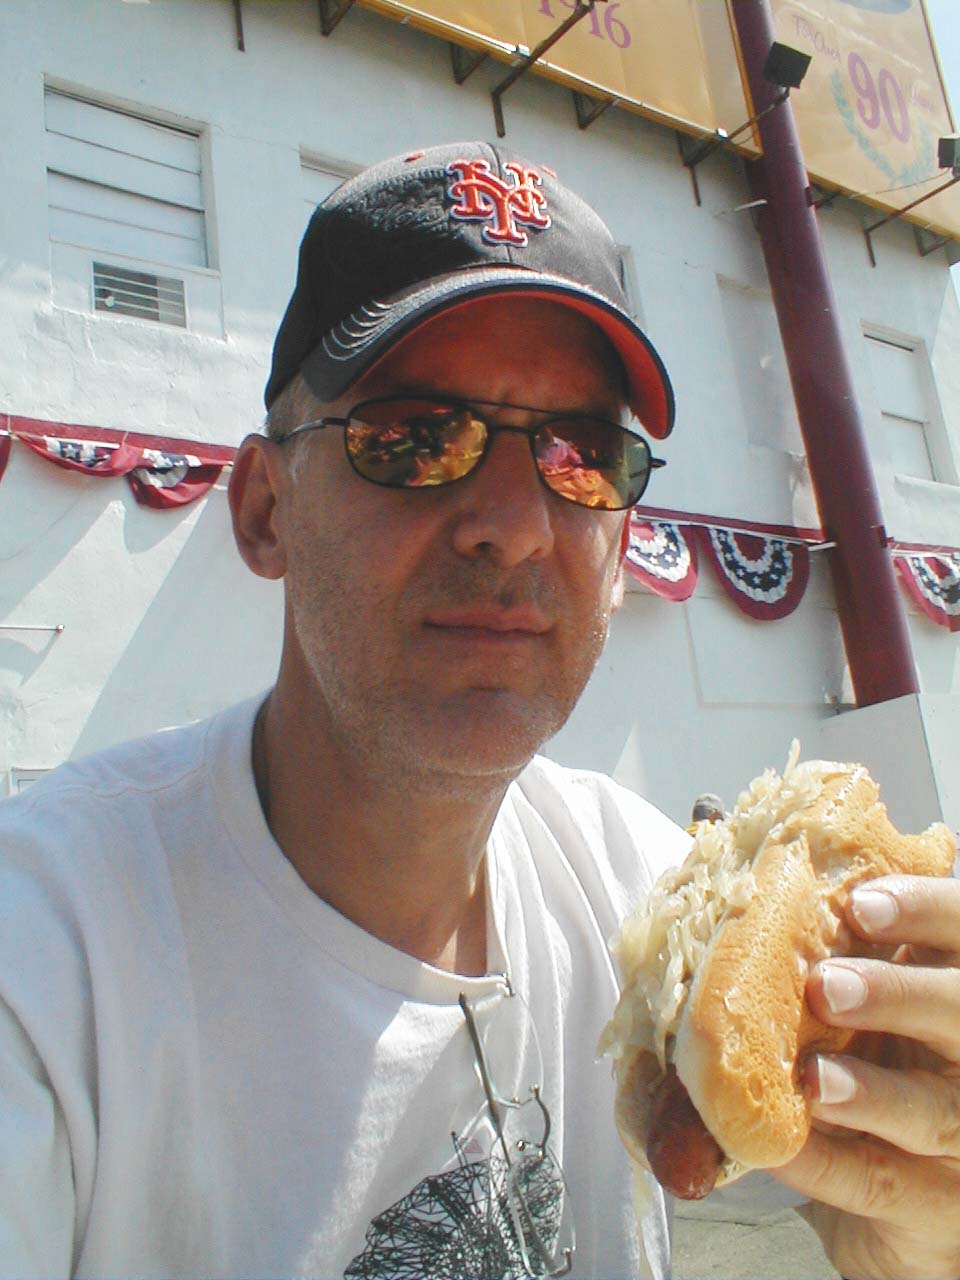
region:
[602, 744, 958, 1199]
a hot dog with wiener and sauerkraut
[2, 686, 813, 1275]
a white shirt with a black logo on it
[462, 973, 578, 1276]
a pair of glasses with silver frame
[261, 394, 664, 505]
sunglasses with black frame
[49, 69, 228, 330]
a white vent below a window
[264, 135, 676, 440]
a black cap with an orange logo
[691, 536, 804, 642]
flag on the building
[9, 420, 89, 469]
flag on the building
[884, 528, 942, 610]
flag on the building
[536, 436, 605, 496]
glasses on the man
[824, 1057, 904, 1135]
finger on the hand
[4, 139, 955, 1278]
a man wearing a baseball hat with the initials N and Y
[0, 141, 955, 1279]
man has a pair of glasses hanging from his shirt collar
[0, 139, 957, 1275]
man's sunglasses are reflective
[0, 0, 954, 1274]
tall white wall behind man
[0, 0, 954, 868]
wall has patriotic bunting on it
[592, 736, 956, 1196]
hotdog bun has a bite-sized piece missing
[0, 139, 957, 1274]
man's face is unshaven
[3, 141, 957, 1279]
man's white shirt has a black design on it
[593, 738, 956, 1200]
hot dog with saurkraut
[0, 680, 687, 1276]
white t-shirt with black design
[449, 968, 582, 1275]
dangling reading glasses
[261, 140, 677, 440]
New York ball cap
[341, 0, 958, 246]
large yellow billboard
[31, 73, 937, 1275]
man eating a hot dog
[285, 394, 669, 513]
reflective sunglasses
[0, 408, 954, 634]
red, white, and blue patriotic decorations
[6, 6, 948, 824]
building painted white and decorated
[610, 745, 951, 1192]
A partially eaten hot dog.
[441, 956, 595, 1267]
Eyeglasses hanging from neck of shirt.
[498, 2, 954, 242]
Large yellow and red sign.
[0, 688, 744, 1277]
A white tee shirt.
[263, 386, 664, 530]
Dark framed sunglasses.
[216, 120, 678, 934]
Man wearing black cap.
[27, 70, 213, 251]
A shuttered window.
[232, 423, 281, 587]
A person's right ear.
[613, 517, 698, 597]
red white and blue flag behind the man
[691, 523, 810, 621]
red white and blue flag behind the man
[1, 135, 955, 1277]
A man wearing a New York hat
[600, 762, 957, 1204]
A hot dog missing a bite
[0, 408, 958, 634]
A red, white, and blue banner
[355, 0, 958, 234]
A yellow sign with red writing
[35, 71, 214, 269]
A window with white louvers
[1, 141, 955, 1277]
A man wearing reflective sunglasses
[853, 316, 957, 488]
A white covered window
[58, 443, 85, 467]
white star on flag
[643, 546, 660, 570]
white star on flag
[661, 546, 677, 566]
white star on flag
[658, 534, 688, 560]
white star on flag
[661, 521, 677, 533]
white star on flag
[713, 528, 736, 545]
white star on flag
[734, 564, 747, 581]
white star on flag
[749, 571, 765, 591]
white star on flag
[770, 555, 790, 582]
white star on flag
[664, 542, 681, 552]
white star on flag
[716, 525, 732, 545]
white star on flag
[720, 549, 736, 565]
white star on flag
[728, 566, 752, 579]
white star on flag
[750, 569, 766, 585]
white star on flag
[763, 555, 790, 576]
white star on flag